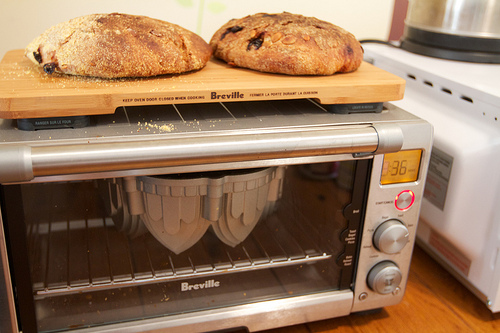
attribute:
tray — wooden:
[9, 37, 405, 116]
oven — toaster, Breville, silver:
[12, 119, 426, 329]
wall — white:
[12, 4, 411, 41]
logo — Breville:
[176, 277, 236, 315]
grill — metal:
[26, 239, 329, 279]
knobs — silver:
[358, 214, 418, 304]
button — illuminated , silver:
[387, 186, 416, 213]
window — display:
[378, 142, 418, 185]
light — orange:
[378, 149, 428, 197]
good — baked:
[217, 10, 359, 88]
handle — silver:
[20, 131, 390, 183]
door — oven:
[10, 121, 371, 321]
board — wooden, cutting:
[5, 69, 403, 110]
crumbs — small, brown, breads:
[124, 119, 187, 148]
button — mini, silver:
[354, 284, 369, 309]